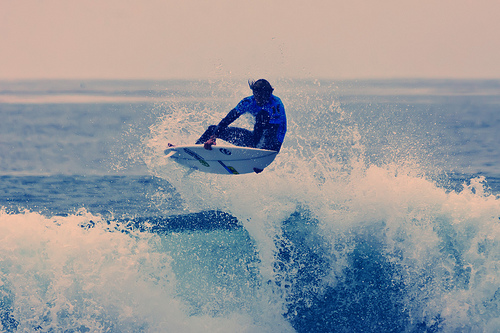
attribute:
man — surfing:
[168, 78, 286, 173]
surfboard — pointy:
[156, 141, 277, 175]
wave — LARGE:
[4, 183, 499, 332]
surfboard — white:
[158, 130, 285, 183]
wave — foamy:
[13, 189, 242, 326]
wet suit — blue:
[207, 96, 284, 145]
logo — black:
[272, 102, 284, 117]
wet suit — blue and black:
[193, 96, 288, 151]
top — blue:
[227, 98, 300, 138]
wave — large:
[295, 66, 485, 314]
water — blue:
[0, 78, 497, 330]